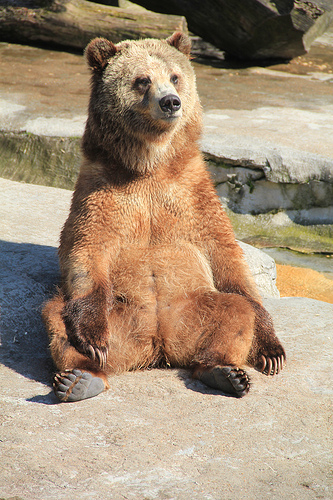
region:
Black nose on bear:
[155, 92, 185, 114]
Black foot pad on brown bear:
[52, 367, 120, 401]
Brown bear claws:
[77, 336, 122, 367]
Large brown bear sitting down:
[27, 21, 293, 409]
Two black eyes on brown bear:
[127, 69, 188, 94]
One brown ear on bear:
[83, 31, 123, 74]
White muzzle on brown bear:
[150, 83, 186, 127]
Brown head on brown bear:
[78, 30, 204, 173]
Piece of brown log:
[0, 4, 202, 67]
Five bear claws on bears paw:
[252, 349, 290, 378]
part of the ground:
[245, 417, 257, 420]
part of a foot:
[238, 372, 240, 383]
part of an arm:
[264, 348, 267, 356]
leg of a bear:
[120, 356, 124, 360]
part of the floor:
[162, 450, 172, 479]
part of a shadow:
[21, 360, 31, 390]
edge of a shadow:
[35, 345, 47, 369]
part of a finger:
[239, 354, 240, 383]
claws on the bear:
[254, 356, 287, 372]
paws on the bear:
[50, 369, 110, 400]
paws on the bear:
[191, 364, 256, 396]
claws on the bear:
[82, 343, 108, 367]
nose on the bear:
[151, 93, 186, 111]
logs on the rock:
[7, 0, 186, 45]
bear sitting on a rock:
[43, 27, 288, 397]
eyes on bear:
[132, 71, 189, 87]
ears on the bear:
[78, 31, 193, 62]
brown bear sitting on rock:
[41, 27, 293, 402]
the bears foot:
[200, 363, 258, 403]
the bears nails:
[89, 344, 115, 366]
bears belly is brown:
[122, 243, 196, 304]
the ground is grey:
[114, 399, 287, 493]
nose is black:
[157, 95, 178, 110]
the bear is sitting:
[43, 39, 282, 404]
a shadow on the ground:
[7, 252, 42, 335]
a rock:
[250, 113, 303, 148]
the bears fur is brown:
[77, 192, 171, 259]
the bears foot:
[54, 370, 108, 401]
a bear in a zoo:
[45, 20, 293, 410]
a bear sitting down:
[51, 24, 287, 414]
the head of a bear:
[73, 31, 206, 132]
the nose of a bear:
[157, 93, 181, 113]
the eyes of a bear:
[132, 69, 184, 86]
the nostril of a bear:
[163, 98, 169, 108]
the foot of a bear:
[49, 364, 103, 403]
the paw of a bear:
[251, 332, 287, 374]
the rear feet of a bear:
[49, 362, 251, 401]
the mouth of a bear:
[158, 114, 180, 119]